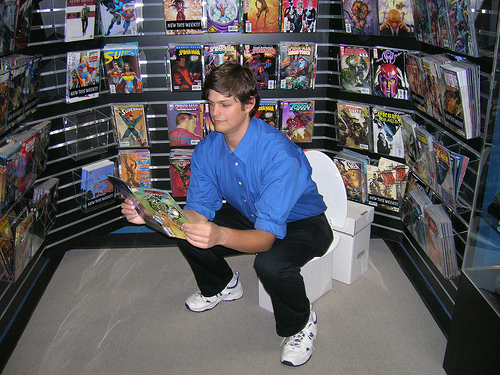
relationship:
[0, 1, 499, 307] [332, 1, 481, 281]
racks hold comics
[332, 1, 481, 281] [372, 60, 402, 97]
comics have superheroes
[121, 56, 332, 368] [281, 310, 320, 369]
man has foot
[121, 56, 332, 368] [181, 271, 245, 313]
man has foot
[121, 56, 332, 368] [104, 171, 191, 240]
man holds comic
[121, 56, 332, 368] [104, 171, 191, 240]
man reads comic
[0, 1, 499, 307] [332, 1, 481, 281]
racks holds comics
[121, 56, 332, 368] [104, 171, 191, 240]
man looks at comic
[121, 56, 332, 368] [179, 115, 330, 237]
man wears shirt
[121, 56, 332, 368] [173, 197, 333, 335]
man wears pants